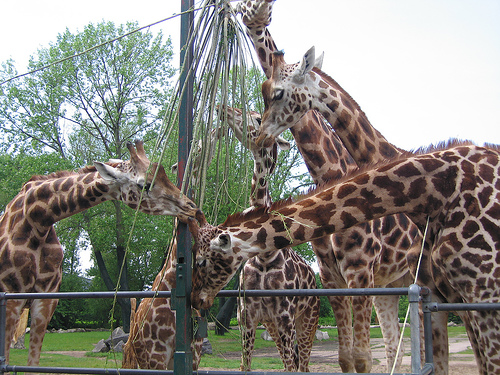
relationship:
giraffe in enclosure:
[6, 148, 201, 353] [1, 288, 499, 372]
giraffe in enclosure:
[6, 148, 201, 353] [3, 277, 498, 374]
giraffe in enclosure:
[205, 99, 327, 373] [1, 2, 498, 369]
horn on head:
[127, 141, 137, 163] [117, 153, 206, 227]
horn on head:
[135, 138, 144, 156] [117, 153, 206, 227]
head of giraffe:
[117, 153, 206, 227] [6, 148, 201, 353]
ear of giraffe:
[92, 159, 128, 186] [6, 148, 201, 353]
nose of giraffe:
[180, 197, 200, 213] [6, 148, 201, 353]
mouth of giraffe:
[213, 107, 318, 159] [246, 37, 498, 327]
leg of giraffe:
[0, 292, 29, 369] [6, 148, 201, 353]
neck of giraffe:
[22, 160, 123, 226] [6, 148, 201, 353]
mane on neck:
[21, 160, 118, 181] [22, 160, 123, 226]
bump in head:
[146, 159, 167, 180] [73, 152, 208, 222]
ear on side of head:
[92, 159, 128, 186] [88, 142, 203, 223]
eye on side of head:
[263, 89, 288, 108] [239, 45, 347, 155]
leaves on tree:
[40, 33, 78, 71] [19, 13, 160, 318]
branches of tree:
[51, 53, 112, 145] [19, 13, 160, 318]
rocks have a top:
[88, 324, 130, 356] [105, 321, 130, 336]